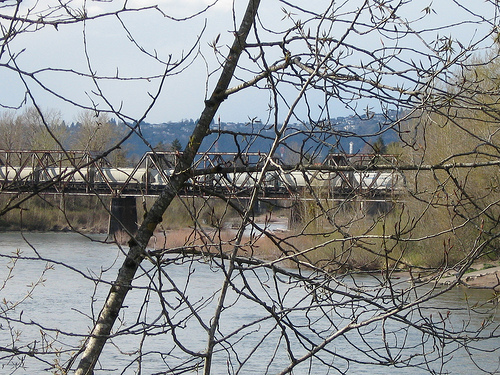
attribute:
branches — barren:
[176, 195, 353, 361]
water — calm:
[312, 319, 412, 360]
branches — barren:
[116, 80, 403, 335]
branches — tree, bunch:
[8, 28, 479, 363]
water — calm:
[45, 284, 79, 318]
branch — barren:
[153, 247, 498, 344]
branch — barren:
[191, 170, 364, 317]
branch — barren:
[218, 50, 326, 100]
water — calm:
[33, 234, 124, 276]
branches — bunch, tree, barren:
[0, 1, 497, 373]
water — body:
[4, 216, 494, 373]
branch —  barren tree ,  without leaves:
[272, 238, 469, 364]